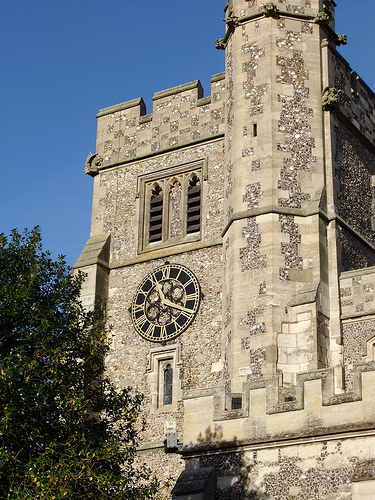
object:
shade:
[166, 421, 255, 499]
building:
[53, 0, 375, 500]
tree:
[0, 221, 182, 500]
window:
[136, 154, 208, 258]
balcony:
[332, 220, 375, 320]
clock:
[127, 258, 205, 346]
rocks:
[350, 190, 359, 205]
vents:
[186, 214, 200, 223]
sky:
[0, 0, 230, 292]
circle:
[170, 284, 185, 301]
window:
[145, 343, 184, 416]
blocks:
[281, 165, 290, 177]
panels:
[148, 205, 162, 213]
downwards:
[148, 233, 162, 242]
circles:
[146, 303, 160, 321]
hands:
[152, 271, 166, 300]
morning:
[0, 0, 375, 302]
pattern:
[100, 78, 226, 167]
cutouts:
[141, 114, 147, 116]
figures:
[222, 2, 241, 30]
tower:
[213, 0, 350, 418]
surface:
[110, 125, 219, 161]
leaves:
[18, 266, 23, 271]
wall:
[70, 0, 375, 500]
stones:
[244, 91, 252, 104]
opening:
[196, 75, 212, 107]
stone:
[266, 83, 307, 143]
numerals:
[167, 272, 168, 273]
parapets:
[161, 101, 169, 108]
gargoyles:
[321, 85, 347, 110]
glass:
[163, 367, 173, 405]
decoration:
[238, 214, 304, 274]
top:
[213, 0, 349, 55]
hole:
[252, 122, 258, 139]